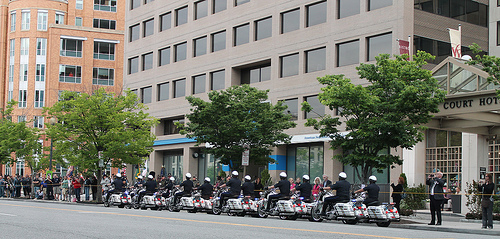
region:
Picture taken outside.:
[17, 10, 482, 224]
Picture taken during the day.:
[34, 25, 481, 140]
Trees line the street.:
[11, 109, 489, 159]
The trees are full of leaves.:
[43, 99, 422, 142]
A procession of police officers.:
[60, 164, 418, 236]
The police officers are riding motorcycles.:
[106, 159, 409, 208]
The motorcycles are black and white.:
[91, 140, 436, 230]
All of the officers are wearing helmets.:
[95, 155, 382, 224]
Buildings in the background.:
[33, 14, 379, 96]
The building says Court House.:
[420, 33, 497, 119]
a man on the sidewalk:
[418, 165, 449, 228]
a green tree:
[31, 82, 167, 216]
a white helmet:
[112, 170, 124, 181]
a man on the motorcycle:
[212, 166, 241, 213]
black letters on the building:
[438, 93, 498, 110]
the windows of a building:
[53, 32, 87, 59]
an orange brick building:
[0, 0, 136, 195]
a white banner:
[441, 21, 463, 61]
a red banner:
[396, 34, 410, 68]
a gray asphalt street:
[0, 194, 499, 237]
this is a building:
[13, 2, 113, 92]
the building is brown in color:
[46, 36, 56, 84]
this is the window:
[60, 37, 80, 54]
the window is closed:
[95, 40, 116, 54]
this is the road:
[11, 200, 85, 237]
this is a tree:
[56, 90, 137, 153]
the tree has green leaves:
[220, 115, 239, 130]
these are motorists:
[116, 173, 379, 218]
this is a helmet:
[338, 170, 345, 177]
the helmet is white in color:
[281, 171, 283, 176]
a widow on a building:
[128, 23, 143, 37]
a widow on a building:
[368, 34, 393, 54]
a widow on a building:
[333, 35, 360, 68]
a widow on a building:
[299, 46, 333, 71]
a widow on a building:
[276, 52, 303, 75]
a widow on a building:
[303, 94, 328, 117]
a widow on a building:
[270, 93, 299, 118]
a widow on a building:
[208, 67, 223, 91]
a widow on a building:
[191, 74, 208, 95]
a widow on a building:
[174, 74, 186, 97]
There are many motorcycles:
[87, 154, 474, 231]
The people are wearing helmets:
[105, 163, 400, 191]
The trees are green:
[41, 85, 461, 187]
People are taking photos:
[427, 170, 497, 210]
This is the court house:
[432, 87, 498, 116]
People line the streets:
[1, 174, 173, 217]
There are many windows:
[131, 38, 496, 143]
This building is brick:
[11, 30, 124, 143]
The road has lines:
[26, 205, 113, 236]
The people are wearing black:
[127, 159, 406, 220]